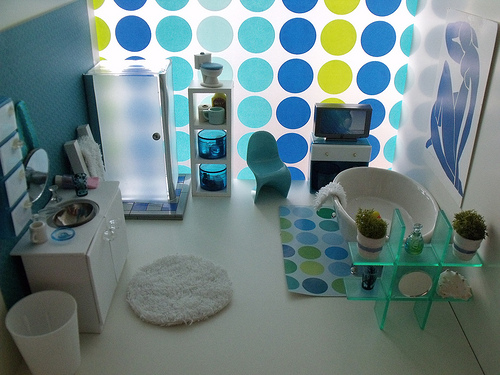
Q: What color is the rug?
A: White.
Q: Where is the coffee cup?
A: By the sink.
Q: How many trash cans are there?
A: One.